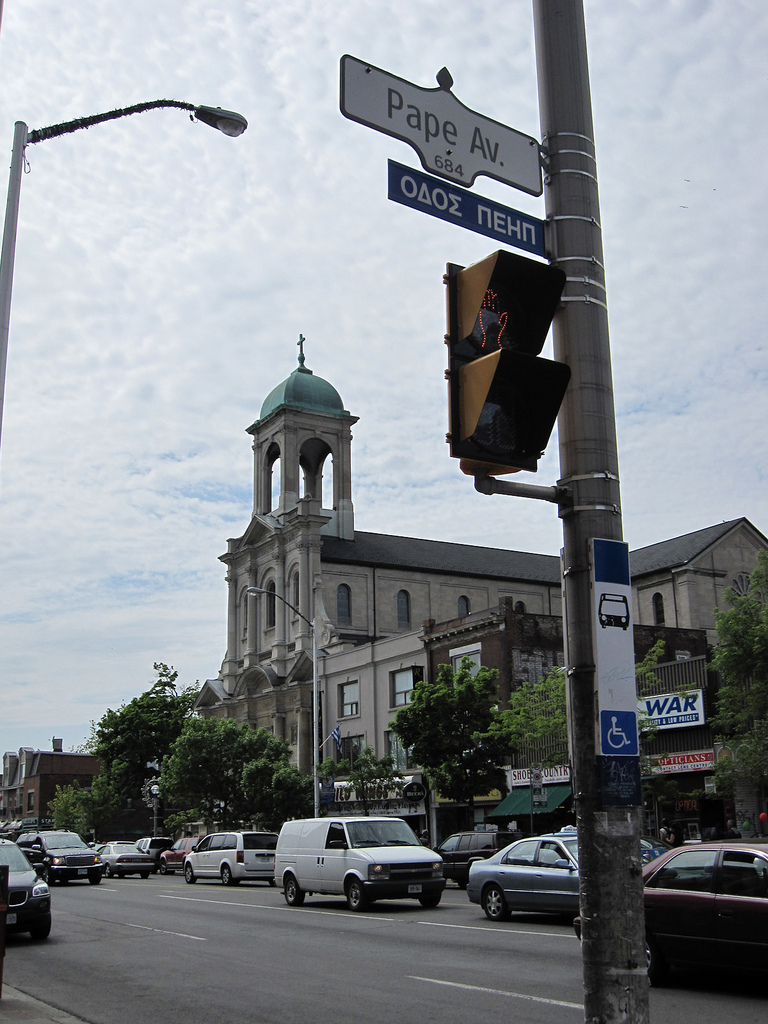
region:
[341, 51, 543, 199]
Grey and white sign that says Pape Av.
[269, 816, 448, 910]
A larger white van.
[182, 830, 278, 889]
A smaller white van behind a larger one.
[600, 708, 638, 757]
Blue square handicapped sign.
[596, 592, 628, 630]
A black outline of a bus.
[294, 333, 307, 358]
Grey cross on a green dome top.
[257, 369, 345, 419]
A green dome on a building.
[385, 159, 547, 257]
Blue rectangle sign on a pole with white symbols.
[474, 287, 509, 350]
An orange LED hand symbol.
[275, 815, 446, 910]
white van driving on the street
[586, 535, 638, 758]
blue ad white sign attached to metal pole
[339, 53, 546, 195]
white street sign attached to metal pole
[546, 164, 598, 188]
silver brackets around gray pole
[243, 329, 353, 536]
belfry on top of church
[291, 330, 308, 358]
cross on top of belfry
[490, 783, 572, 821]
green awning below sign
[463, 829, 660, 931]
silver car in front of van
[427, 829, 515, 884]
car is parked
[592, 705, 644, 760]
a blue and white handicap sign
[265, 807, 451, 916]
a white van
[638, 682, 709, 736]
a blue and white sign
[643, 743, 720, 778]
a red and white sign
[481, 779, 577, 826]
a green awning on the store front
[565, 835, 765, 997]
a red car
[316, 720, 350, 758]
a blue and white flag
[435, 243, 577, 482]
a crosswalk sign on a post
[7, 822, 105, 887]
a black vehicle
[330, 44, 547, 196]
a black and white sign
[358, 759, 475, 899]
A person eating a orange.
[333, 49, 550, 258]
street sign mounted to pole with silver bands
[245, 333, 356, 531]
cross atop of church belfry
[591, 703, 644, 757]
handicap picture on the pole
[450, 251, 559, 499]
pedestrian light on the pole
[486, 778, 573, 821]
green awning on the front of the store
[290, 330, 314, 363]
cross on the top of the building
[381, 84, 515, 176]
Pape Av. written on the street sign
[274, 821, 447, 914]
white van on the road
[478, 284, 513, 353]
picture of a hand lit up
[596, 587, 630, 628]
picture of a bus on the pole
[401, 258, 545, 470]
signal light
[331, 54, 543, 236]
street signs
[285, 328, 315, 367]
cross on top of church tower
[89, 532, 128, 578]
white clouds in blue sky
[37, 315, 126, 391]
white clouds in blue sky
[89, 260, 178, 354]
white clouds in blue sky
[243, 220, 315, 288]
white clouds in blue sky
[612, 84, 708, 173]
white clouds in blue sky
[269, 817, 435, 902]
white van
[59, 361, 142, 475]
white clouds in blue sky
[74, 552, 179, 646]
white clouds in blue sky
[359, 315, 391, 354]
white clouds in blue sky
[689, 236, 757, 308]
white clouds in blue sky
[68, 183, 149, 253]
white clouds in blue sky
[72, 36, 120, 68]
white clouds in blue sky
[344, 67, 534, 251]
street signs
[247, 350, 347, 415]
green dome on building